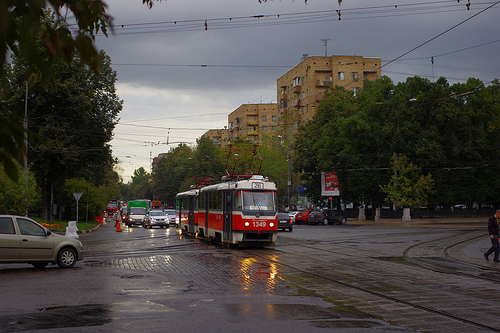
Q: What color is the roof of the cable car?
A: White.